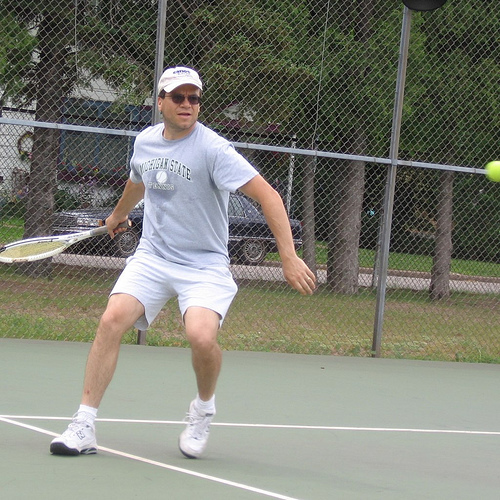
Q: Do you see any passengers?
A: No, there are no passengers.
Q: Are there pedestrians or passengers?
A: No, there are no passengers or pedestrians.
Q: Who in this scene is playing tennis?
A: The man is playing tennis.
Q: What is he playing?
A: The man is playing tennis.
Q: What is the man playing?
A: The man is playing tennis.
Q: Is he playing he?
A: Yes, the man is playing tennis.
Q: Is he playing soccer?
A: No, the man is playing tennis.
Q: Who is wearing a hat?
A: The man is wearing a hat.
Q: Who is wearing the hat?
A: The man is wearing a hat.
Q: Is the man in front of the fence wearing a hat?
A: Yes, the man is wearing a hat.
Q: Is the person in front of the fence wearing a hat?
A: Yes, the man is wearing a hat.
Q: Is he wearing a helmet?
A: No, the man is wearing a hat.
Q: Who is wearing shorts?
A: The man is wearing shorts.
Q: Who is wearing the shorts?
A: The man is wearing shorts.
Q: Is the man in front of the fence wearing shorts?
A: Yes, the man is wearing shorts.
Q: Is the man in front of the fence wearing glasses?
A: No, the man is wearing shorts.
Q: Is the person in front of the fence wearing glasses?
A: No, the man is wearing shorts.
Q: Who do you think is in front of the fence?
A: The man is in front of the fence.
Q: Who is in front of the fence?
A: The man is in front of the fence.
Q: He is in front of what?
A: The man is in front of the fence.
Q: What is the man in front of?
A: The man is in front of the fence.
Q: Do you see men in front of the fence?
A: Yes, there is a man in front of the fence.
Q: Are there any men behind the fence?
A: No, the man is in front of the fence.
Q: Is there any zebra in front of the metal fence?
A: No, there is a man in front of the fence.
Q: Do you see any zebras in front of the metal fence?
A: No, there is a man in front of the fence.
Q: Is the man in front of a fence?
A: Yes, the man is in front of a fence.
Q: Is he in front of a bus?
A: No, the man is in front of a fence.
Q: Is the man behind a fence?
A: No, the man is in front of a fence.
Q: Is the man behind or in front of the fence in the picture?
A: The man is in front of the fence.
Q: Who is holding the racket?
A: The man is holding the tennis racket.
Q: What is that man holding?
A: The man is holding the racket.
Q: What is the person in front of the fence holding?
A: The man is holding the racket.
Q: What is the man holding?
A: The man is holding the racket.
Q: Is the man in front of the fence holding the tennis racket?
A: Yes, the man is holding the tennis racket.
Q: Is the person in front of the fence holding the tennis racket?
A: Yes, the man is holding the tennis racket.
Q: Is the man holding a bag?
A: No, the man is holding the tennis racket.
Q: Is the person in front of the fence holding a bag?
A: No, the man is holding the tennis racket.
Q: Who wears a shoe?
A: The man wears a shoe.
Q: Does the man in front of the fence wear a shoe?
A: Yes, the man wears a shoe.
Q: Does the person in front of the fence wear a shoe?
A: Yes, the man wears a shoe.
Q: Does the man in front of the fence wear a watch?
A: No, the man wears a shoe.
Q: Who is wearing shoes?
A: The man is wearing shoes.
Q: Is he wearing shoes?
A: Yes, the man is wearing shoes.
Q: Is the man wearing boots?
A: No, the man is wearing shoes.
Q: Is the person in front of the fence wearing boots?
A: No, the man is wearing shoes.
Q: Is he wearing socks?
A: Yes, the man is wearing socks.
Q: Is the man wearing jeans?
A: No, the man is wearing socks.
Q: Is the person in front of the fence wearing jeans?
A: No, the man is wearing socks.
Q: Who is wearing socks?
A: The man is wearing socks.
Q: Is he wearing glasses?
A: No, the man is wearing socks.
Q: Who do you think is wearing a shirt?
A: The man is wearing a shirt.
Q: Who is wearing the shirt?
A: The man is wearing a shirt.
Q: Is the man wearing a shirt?
A: Yes, the man is wearing a shirt.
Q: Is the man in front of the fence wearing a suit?
A: No, the man is wearing a shirt.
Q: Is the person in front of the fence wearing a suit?
A: No, the man is wearing a shirt.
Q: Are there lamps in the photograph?
A: No, there are no lamps.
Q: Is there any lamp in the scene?
A: No, there are no lamps.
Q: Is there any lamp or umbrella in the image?
A: No, there are no lamps or umbrellas.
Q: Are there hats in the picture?
A: Yes, there is a hat.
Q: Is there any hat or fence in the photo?
A: Yes, there is a hat.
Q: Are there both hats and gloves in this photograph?
A: No, there is a hat but no gloves.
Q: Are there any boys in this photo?
A: No, there are no boys.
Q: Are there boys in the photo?
A: No, there are no boys.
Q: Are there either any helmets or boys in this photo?
A: No, there are no boys or helmets.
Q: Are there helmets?
A: No, there are no helmets.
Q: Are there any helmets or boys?
A: No, there are no helmets or boys.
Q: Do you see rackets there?
A: Yes, there is a racket.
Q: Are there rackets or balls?
A: Yes, there is a racket.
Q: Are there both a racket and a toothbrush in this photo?
A: No, there is a racket but no toothbrushes.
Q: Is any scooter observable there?
A: No, there are no scooters.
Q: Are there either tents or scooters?
A: No, there are no scooters or tents.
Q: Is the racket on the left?
A: Yes, the racket is on the left of the image.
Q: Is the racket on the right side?
A: No, the racket is on the left of the image.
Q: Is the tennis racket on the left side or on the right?
A: The tennis racket is on the left of the image.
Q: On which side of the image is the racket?
A: The racket is on the left of the image.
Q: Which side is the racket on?
A: The racket is on the left of the image.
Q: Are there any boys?
A: No, there are no boys.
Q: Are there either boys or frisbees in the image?
A: No, there are no boys or frisbees.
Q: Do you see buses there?
A: No, there are no buses.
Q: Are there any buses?
A: No, there are no buses.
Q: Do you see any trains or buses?
A: No, there are no buses or trains.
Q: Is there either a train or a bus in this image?
A: No, there are no buses or trains.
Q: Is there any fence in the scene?
A: Yes, there is a fence.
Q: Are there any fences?
A: Yes, there is a fence.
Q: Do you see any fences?
A: Yes, there is a fence.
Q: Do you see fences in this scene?
A: Yes, there is a fence.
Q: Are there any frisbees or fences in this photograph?
A: Yes, there is a fence.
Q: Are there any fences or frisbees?
A: Yes, there is a fence.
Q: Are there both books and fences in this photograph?
A: No, there is a fence but no books.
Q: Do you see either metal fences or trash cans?
A: Yes, there is a metal fence.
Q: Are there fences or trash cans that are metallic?
A: Yes, the fence is metallic.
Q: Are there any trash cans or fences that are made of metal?
A: Yes, the fence is made of metal.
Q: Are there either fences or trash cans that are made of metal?
A: Yes, the fence is made of metal.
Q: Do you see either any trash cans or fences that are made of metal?
A: Yes, the fence is made of metal.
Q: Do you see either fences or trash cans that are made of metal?
A: Yes, the fence is made of metal.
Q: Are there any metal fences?
A: Yes, there is a metal fence.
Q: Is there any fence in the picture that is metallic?
A: Yes, there is a fence that is metallic.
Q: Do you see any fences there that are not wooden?
A: Yes, there is a metallic fence.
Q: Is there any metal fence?
A: Yes, there is a fence that is made of metal.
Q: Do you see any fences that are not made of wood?
A: Yes, there is a fence that is made of metal.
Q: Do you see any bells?
A: No, there are no bells.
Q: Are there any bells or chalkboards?
A: No, there are no bells or chalkboards.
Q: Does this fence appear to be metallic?
A: Yes, the fence is metallic.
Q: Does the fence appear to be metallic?
A: Yes, the fence is metallic.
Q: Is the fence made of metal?
A: Yes, the fence is made of metal.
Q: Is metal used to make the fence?
A: Yes, the fence is made of metal.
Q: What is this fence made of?
A: The fence is made of metal.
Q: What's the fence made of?
A: The fence is made of metal.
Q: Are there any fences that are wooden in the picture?
A: No, there is a fence but it is metallic.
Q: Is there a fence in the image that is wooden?
A: No, there is a fence but it is metallic.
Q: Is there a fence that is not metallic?
A: No, there is a fence but it is metallic.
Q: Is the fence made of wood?
A: No, the fence is made of metal.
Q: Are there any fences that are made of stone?
A: No, there is a fence but it is made of metal.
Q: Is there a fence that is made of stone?
A: No, there is a fence but it is made of metal.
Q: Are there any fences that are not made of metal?
A: No, there is a fence but it is made of metal.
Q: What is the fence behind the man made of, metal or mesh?
A: The fence is made of metal.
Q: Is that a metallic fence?
A: Yes, that is a metallic fence.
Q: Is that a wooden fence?
A: No, that is a metallic fence.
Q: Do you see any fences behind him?
A: Yes, there is a fence behind the man.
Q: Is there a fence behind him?
A: Yes, there is a fence behind the man.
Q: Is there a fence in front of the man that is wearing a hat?
A: No, the fence is behind the man.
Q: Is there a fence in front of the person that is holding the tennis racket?
A: No, the fence is behind the man.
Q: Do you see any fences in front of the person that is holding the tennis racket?
A: No, the fence is behind the man.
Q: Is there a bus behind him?
A: No, there is a fence behind the man.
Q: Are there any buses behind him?
A: No, there is a fence behind the man.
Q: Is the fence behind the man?
A: Yes, the fence is behind the man.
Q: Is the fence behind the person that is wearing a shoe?
A: Yes, the fence is behind the man.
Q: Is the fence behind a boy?
A: No, the fence is behind the man.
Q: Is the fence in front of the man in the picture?
A: No, the fence is behind the man.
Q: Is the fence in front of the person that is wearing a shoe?
A: No, the fence is behind the man.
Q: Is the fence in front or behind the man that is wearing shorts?
A: The fence is behind the man.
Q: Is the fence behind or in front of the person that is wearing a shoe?
A: The fence is behind the man.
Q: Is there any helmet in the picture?
A: No, there are no helmets.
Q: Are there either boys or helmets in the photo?
A: No, there are no helmets or boys.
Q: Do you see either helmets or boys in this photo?
A: No, there are no helmets or boys.